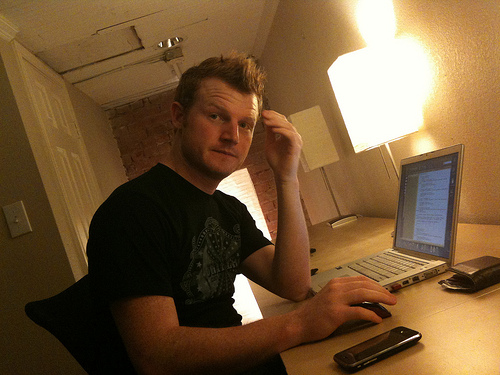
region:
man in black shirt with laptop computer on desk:
[110, 74, 450, 339]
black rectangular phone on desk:
[324, 327, 431, 367]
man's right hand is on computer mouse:
[301, 276, 393, 328]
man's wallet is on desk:
[441, 241, 494, 302]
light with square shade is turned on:
[311, 45, 450, 149]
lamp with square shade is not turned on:
[281, 100, 345, 195]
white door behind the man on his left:
[3, 46, 103, 286]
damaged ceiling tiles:
[33, 10, 153, 68]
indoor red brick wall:
[106, 92, 169, 160]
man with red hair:
[150, 37, 297, 189]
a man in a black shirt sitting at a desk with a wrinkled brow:
[90, 54, 394, 372]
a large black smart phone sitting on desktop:
[327, 326, 422, 371]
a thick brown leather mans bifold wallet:
[437, 255, 498, 295]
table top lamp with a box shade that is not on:
[288, 100, 358, 232]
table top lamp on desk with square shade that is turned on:
[325, 45, 430, 237]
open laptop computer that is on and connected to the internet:
[306, 141, 469, 299]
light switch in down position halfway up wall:
[0, 197, 34, 240]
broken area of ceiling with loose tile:
[37, 19, 146, 76]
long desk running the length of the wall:
[245, 202, 497, 371]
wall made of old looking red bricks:
[112, 70, 179, 180]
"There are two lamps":
[274, 1, 481, 230]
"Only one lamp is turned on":
[281, 11, 463, 261]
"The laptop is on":
[296, 136, 479, 324]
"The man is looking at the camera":
[101, 21, 378, 351]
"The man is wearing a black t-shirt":
[83, 56, 317, 362]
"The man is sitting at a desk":
[103, 40, 498, 373]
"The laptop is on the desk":
[291, 136, 466, 306]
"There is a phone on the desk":
[325, 309, 441, 371]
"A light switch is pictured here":
[1, 186, 47, 249]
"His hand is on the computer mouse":
[73, 46, 403, 348]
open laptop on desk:
[294, 138, 474, 298]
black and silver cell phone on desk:
[324, 318, 432, 374]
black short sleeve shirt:
[76, 158, 276, 370]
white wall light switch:
[1, 196, 37, 241]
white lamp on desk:
[321, 41, 455, 236]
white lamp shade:
[321, 53, 426, 155]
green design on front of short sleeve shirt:
[183, 206, 244, 321]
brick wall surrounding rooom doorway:
[108, 91, 305, 251]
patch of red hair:
[173, 52, 270, 97]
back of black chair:
[19, 275, 109, 372]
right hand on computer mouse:
[287, 262, 406, 354]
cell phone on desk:
[324, 316, 434, 374]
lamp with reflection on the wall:
[311, 48, 446, 155]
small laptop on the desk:
[291, 121, 470, 318]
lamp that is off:
[281, 96, 351, 240]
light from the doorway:
[208, 161, 276, 326]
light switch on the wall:
[0, 187, 39, 243]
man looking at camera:
[73, 49, 398, 363]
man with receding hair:
[170, 55, 275, 177]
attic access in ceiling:
[32, 15, 154, 90]